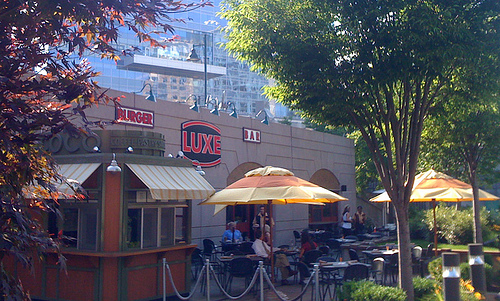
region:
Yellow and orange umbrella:
[212, 153, 347, 217]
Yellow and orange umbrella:
[352, 150, 498, 217]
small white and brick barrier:
[425, 243, 470, 299]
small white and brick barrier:
[460, 240, 488, 300]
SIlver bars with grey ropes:
[148, 250, 330, 296]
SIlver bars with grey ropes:
[155, 253, 204, 300]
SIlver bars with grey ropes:
[202, 253, 240, 298]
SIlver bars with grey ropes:
[256, 255, 281, 298]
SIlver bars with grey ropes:
[307, 260, 323, 299]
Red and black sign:
[177, 112, 246, 173]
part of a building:
[234, 136, 244, 160]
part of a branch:
[393, 172, 409, 197]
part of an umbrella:
[289, 188, 295, 195]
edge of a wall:
[246, 148, 252, 161]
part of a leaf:
[48, 238, 67, 262]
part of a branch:
[463, 138, 475, 157]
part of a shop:
[114, 228, 119, 258]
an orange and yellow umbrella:
[204, 165, 409, 242]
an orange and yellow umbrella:
[369, 150, 489, 205]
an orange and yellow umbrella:
[233, 163, 320, 204]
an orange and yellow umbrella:
[386, 169, 495, 220]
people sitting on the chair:
[248, 229, 331, 261]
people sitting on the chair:
[223, 210, 283, 276]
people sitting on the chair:
[218, 213, 357, 292]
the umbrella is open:
[186, 158, 346, 228]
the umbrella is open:
[372, 163, 495, 202]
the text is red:
[174, 115, 228, 174]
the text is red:
[240, 131, 262, 146]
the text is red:
[166, 114, 256, 204]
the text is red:
[241, 120, 262, 143]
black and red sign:
[178, 114, 228, 161]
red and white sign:
[112, 97, 152, 126]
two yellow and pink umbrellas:
[207, 160, 490, 232]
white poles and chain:
[155, 250, 340, 300]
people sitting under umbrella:
[243, 224, 326, 279]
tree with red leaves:
[2, 7, 182, 264]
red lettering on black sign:
[173, 113, 225, 168]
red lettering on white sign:
[113, 101, 150, 131]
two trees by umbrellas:
[264, 5, 491, 282]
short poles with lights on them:
[430, 240, 482, 300]